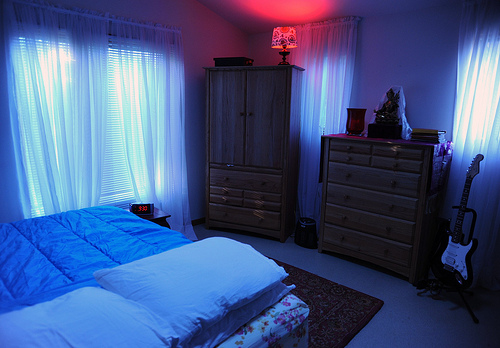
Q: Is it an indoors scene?
A: Yes, it is indoors.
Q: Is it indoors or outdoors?
A: It is indoors.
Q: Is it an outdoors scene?
A: No, it is indoors.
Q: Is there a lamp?
A: Yes, there is a lamp.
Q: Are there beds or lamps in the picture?
A: Yes, there is a lamp.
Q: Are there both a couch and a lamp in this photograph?
A: No, there is a lamp but no couches.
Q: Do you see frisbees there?
A: No, there are no frisbees.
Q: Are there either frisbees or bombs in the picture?
A: No, there are no frisbees or bombs.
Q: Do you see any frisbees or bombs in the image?
A: No, there are no frisbees or bombs.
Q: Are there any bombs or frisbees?
A: No, there are no frisbees or bombs.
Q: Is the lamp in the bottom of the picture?
A: No, the lamp is in the top of the image.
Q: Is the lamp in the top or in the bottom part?
A: The lamp is in the top of the image.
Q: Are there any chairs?
A: No, there are no chairs.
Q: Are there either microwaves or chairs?
A: No, there are no chairs or microwaves.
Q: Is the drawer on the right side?
A: Yes, the drawer is on the right of the image.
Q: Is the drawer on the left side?
A: No, the drawer is on the right of the image.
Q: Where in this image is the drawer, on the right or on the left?
A: The drawer is on the right of the image.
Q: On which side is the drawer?
A: The drawer is on the right of the image.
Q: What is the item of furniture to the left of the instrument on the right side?
A: The piece of furniture is a drawer.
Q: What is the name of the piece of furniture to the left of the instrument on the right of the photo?
A: The piece of furniture is a drawer.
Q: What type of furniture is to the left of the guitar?
A: The piece of furniture is a drawer.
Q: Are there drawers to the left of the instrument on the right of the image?
A: Yes, there is a drawer to the left of the guitar.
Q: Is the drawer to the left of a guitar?
A: Yes, the drawer is to the left of a guitar.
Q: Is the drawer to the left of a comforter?
A: No, the drawer is to the left of a guitar.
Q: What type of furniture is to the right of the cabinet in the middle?
A: The piece of furniture is a drawer.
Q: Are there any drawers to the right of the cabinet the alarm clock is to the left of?
A: Yes, there is a drawer to the right of the cabinet.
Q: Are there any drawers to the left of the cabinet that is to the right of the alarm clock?
A: No, the drawer is to the right of the cabinet.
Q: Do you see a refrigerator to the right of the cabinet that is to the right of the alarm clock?
A: No, there is a drawer to the right of the cabinet.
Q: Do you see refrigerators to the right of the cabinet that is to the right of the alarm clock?
A: No, there is a drawer to the right of the cabinet.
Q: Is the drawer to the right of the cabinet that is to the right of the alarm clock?
A: Yes, the drawer is to the right of the cabinet.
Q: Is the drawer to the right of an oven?
A: No, the drawer is to the right of the cabinet.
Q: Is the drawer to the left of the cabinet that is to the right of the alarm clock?
A: No, the drawer is to the right of the cabinet.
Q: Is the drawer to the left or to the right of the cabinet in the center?
A: The drawer is to the right of the cabinet.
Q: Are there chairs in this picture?
A: No, there are no chairs.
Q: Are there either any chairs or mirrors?
A: No, there are no chairs or mirrors.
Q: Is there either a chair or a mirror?
A: No, there are no chairs or mirrors.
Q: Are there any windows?
A: Yes, there is a window.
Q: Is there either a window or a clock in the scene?
A: Yes, there is a window.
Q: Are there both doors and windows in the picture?
A: Yes, there are both a window and a door.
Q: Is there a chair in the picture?
A: No, there are no chairs.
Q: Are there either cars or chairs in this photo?
A: No, there are no chairs or cars.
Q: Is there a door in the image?
A: Yes, there are doors.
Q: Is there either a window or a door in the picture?
A: Yes, there are doors.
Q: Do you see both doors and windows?
A: Yes, there are both doors and windows.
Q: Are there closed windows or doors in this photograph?
A: Yes, there are closed doors.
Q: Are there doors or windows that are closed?
A: Yes, the doors are closed.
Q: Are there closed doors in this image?
A: Yes, there are closed doors.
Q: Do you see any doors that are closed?
A: Yes, there are closed doors.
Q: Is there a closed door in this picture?
A: Yes, there are closed doors.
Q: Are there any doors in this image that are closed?
A: Yes, there are doors that are closed.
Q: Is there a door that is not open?
A: Yes, there are closed doors.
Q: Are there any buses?
A: No, there are no buses.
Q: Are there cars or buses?
A: No, there are no buses or cars.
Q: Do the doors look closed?
A: Yes, the doors are closed.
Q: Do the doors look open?
A: No, the doors are closed.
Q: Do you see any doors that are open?
A: No, there are doors but they are closed.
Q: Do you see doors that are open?
A: No, there are doors but they are closed.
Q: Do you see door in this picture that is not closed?
A: No, there are doors but they are closed.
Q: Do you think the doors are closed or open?
A: The doors are closed.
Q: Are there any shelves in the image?
A: No, there are no shelves.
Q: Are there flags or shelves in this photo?
A: No, there are no shelves or flags.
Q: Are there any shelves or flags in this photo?
A: No, there are no shelves or flags.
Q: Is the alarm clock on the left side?
A: Yes, the alarm clock is on the left of the image.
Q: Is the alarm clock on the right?
A: No, the alarm clock is on the left of the image.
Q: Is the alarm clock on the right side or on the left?
A: The alarm clock is on the left of the image.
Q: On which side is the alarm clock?
A: The alarm clock is on the left of the image.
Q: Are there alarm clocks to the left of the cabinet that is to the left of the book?
A: Yes, there is an alarm clock to the left of the cabinet.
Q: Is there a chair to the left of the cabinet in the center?
A: No, there is an alarm clock to the left of the cabinet.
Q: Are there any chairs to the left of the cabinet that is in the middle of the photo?
A: No, there is an alarm clock to the left of the cabinet.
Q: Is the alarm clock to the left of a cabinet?
A: Yes, the alarm clock is to the left of a cabinet.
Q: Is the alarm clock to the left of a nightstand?
A: No, the alarm clock is to the left of a cabinet.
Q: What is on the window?
A: The blinds are on the window.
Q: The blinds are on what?
A: The blinds are on the window.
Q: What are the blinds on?
A: The blinds are on the window.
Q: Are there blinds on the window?
A: Yes, there are blinds on the window.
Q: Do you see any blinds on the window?
A: Yes, there are blinds on the window.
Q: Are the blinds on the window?
A: Yes, the blinds are on the window.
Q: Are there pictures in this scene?
A: No, there are no pictures.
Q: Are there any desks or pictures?
A: No, there are no pictures or desks.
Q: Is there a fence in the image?
A: No, there are no fences.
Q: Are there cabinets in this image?
A: Yes, there is a cabinet.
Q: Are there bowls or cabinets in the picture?
A: Yes, there is a cabinet.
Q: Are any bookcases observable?
A: No, there are no bookcases.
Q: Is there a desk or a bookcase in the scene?
A: No, there are no bookcases or desks.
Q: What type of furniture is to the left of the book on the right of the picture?
A: The piece of furniture is a cabinet.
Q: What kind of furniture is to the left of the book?
A: The piece of furniture is a cabinet.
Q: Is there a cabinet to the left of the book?
A: Yes, there is a cabinet to the left of the book.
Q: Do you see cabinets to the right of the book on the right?
A: No, the cabinet is to the left of the book.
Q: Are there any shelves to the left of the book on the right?
A: No, there is a cabinet to the left of the book.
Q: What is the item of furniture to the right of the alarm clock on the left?
A: The piece of furniture is a cabinet.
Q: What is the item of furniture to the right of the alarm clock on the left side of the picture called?
A: The piece of furniture is a cabinet.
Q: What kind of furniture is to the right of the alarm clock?
A: The piece of furniture is a cabinet.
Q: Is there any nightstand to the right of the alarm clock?
A: No, there is a cabinet to the right of the alarm clock.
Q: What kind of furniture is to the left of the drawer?
A: The piece of furniture is a cabinet.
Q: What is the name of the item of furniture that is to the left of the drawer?
A: The piece of furniture is a cabinet.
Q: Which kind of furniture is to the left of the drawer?
A: The piece of furniture is a cabinet.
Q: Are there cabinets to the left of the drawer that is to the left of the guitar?
A: Yes, there is a cabinet to the left of the drawer.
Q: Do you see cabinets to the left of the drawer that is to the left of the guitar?
A: Yes, there is a cabinet to the left of the drawer.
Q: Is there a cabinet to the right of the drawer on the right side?
A: No, the cabinet is to the left of the drawer.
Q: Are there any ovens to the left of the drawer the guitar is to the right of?
A: No, there is a cabinet to the left of the drawer.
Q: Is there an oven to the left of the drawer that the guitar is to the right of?
A: No, there is a cabinet to the left of the drawer.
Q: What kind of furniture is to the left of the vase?
A: The piece of furniture is a cabinet.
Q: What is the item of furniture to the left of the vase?
A: The piece of furniture is a cabinet.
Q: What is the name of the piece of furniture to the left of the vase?
A: The piece of furniture is a cabinet.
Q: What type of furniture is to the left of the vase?
A: The piece of furniture is a cabinet.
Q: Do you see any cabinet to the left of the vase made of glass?
A: Yes, there is a cabinet to the left of the vase.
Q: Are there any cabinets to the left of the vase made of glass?
A: Yes, there is a cabinet to the left of the vase.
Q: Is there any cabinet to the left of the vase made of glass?
A: Yes, there is a cabinet to the left of the vase.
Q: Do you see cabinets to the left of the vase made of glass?
A: Yes, there is a cabinet to the left of the vase.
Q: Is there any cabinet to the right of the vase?
A: No, the cabinet is to the left of the vase.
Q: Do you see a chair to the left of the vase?
A: No, there is a cabinet to the left of the vase.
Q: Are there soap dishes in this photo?
A: No, there are no soap dishes.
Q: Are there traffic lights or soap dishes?
A: No, there are no soap dishes or traffic lights.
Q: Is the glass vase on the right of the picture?
A: Yes, the vase is on the right of the image.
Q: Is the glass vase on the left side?
A: No, the vase is on the right of the image.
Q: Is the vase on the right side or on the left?
A: The vase is on the right of the image.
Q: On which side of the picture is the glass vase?
A: The vase is on the right of the image.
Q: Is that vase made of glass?
A: Yes, the vase is made of glass.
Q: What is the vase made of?
A: The vase is made of glass.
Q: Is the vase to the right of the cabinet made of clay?
A: No, the vase is made of glass.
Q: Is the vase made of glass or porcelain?
A: The vase is made of glass.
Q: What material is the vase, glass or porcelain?
A: The vase is made of glass.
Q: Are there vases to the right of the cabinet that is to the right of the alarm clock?
A: Yes, there is a vase to the right of the cabinet.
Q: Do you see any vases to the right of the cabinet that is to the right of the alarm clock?
A: Yes, there is a vase to the right of the cabinet.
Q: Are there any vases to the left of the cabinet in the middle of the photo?
A: No, the vase is to the right of the cabinet.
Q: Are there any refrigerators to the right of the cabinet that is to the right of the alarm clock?
A: No, there is a vase to the right of the cabinet.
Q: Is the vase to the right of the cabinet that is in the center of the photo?
A: Yes, the vase is to the right of the cabinet.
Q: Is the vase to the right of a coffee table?
A: No, the vase is to the right of the cabinet.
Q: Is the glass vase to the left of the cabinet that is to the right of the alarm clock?
A: No, the vase is to the right of the cabinet.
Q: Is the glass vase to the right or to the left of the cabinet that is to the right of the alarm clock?
A: The vase is to the right of the cabinet.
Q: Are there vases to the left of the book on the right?
A: Yes, there is a vase to the left of the book.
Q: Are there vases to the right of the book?
A: No, the vase is to the left of the book.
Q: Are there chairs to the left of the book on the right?
A: No, there is a vase to the left of the book.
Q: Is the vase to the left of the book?
A: Yes, the vase is to the left of the book.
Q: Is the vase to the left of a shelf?
A: No, the vase is to the left of the book.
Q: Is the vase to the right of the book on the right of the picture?
A: No, the vase is to the left of the book.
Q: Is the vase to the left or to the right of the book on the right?
A: The vase is to the left of the book.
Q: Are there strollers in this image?
A: No, there are no strollers.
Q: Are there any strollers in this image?
A: No, there are no strollers.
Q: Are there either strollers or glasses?
A: No, there are no strollers or glasses.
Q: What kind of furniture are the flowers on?
A: The flowers are on the bed.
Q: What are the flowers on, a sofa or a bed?
A: The flowers are on a bed.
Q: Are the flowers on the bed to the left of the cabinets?
A: Yes, the flowers are on the bed.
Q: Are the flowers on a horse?
A: No, the flowers are on the bed.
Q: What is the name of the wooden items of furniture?
A: The pieces of furniture are cabinets.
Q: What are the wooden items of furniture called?
A: The pieces of furniture are cabinets.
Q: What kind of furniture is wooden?
A: The furniture is cabinets.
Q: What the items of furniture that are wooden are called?
A: The pieces of furniture are cabinets.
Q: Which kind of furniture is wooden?
A: The furniture is cabinets.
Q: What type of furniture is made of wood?
A: The furniture is cabinets.